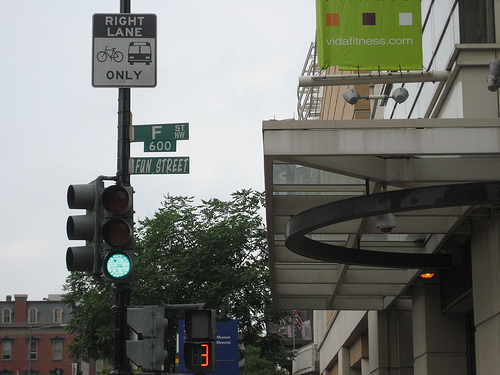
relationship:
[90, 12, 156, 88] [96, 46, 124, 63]
sign has bike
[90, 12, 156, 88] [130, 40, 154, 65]
sign has bus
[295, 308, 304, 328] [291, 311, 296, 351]
flag on pole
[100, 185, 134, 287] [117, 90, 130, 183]
light on pole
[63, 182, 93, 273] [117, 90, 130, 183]
light on pole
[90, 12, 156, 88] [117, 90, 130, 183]
sign on pole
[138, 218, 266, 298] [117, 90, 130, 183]
tree behind pole